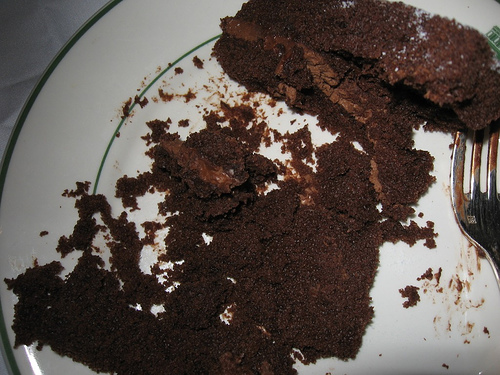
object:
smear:
[431, 240, 490, 345]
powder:
[407, 9, 430, 48]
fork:
[452, 127, 498, 284]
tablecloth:
[4, 15, 54, 68]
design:
[473, 19, 500, 57]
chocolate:
[222, 194, 251, 270]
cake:
[0, 0, 499, 375]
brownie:
[0, 0, 495, 371]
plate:
[0, 0, 499, 375]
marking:
[94, 102, 144, 168]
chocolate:
[87, 321, 151, 372]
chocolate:
[254, 230, 295, 306]